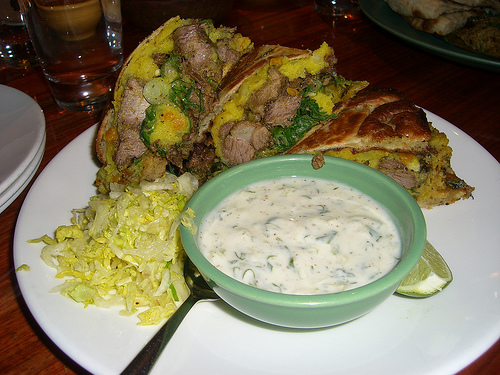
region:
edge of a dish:
[296, 289, 323, 322]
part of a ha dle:
[145, 299, 200, 355]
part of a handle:
[211, 340, 212, 341]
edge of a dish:
[378, 253, 408, 277]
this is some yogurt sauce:
[132, 171, 440, 358]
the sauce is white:
[199, 229, 303, 295]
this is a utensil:
[97, 313, 205, 360]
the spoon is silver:
[101, 291, 200, 369]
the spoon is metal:
[67, 259, 170, 340]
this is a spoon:
[128, 343, 157, 355]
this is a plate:
[67, 289, 124, 361]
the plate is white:
[42, 310, 71, 338]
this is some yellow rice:
[76, 157, 181, 207]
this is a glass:
[47, 25, 104, 83]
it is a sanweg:
[94, 14, 436, 176]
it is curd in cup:
[213, 172, 385, 284]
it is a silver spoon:
[132, 250, 205, 372]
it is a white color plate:
[29, 45, 496, 373]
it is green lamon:
[406, 240, 448, 298]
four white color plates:
[0, 57, 485, 348]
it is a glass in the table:
[14, 2, 119, 108]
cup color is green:
[187, 150, 424, 327]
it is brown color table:
[367, 42, 419, 78]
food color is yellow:
[59, 190, 163, 288]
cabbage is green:
[81, 195, 180, 316]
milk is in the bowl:
[241, 193, 355, 280]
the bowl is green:
[179, 158, 426, 321]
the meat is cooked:
[306, 81, 436, 159]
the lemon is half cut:
[416, 250, 468, 307]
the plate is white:
[231, 339, 479, 373]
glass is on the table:
[22, 5, 129, 110]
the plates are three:
[6, 85, 57, 197]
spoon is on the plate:
[127, 270, 234, 370]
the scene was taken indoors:
[6, 9, 498, 374]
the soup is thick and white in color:
[263, 215, 357, 283]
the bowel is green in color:
[238, 290, 374, 342]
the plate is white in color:
[286, 329, 400, 371]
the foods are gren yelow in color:
[91, 209, 164, 276]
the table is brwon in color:
[4, 314, 56, 373]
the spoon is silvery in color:
[130, 295, 210, 360]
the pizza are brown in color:
[351, 102, 426, 172]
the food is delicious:
[158, 78, 422, 330]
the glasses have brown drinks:
[1, 16, 134, 117]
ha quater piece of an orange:
[423, 253, 452, 300]